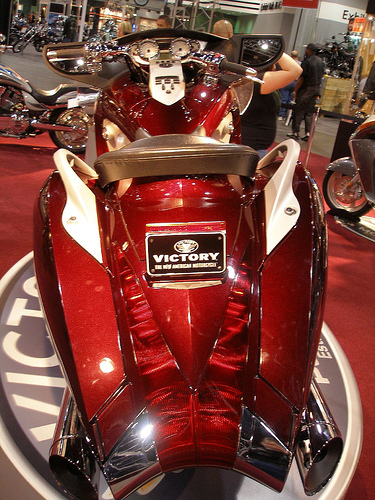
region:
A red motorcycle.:
[21, 11, 347, 495]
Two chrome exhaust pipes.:
[34, 379, 340, 494]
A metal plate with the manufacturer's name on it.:
[130, 216, 235, 291]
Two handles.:
[42, 113, 312, 259]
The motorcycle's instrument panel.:
[115, 30, 214, 75]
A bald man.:
[202, 8, 234, 50]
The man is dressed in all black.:
[282, 30, 328, 143]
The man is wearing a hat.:
[297, 37, 324, 63]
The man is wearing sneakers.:
[277, 111, 317, 149]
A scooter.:
[317, 101, 371, 226]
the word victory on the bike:
[153, 227, 243, 305]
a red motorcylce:
[30, 151, 365, 493]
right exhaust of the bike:
[276, 390, 346, 485]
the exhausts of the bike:
[0, 419, 336, 491]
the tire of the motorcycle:
[336, 114, 372, 198]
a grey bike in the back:
[37, 78, 88, 135]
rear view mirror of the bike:
[240, 16, 318, 75]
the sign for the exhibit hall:
[320, 2, 368, 127]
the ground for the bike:
[16, 313, 80, 451]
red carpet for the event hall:
[340, 253, 374, 352]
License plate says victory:
[144, 233, 225, 275]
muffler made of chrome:
[291, 378, 342, 495]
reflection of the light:
[100, 406, 159, 484]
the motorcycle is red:
[31, 27, 343, 499]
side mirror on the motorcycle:
[40, 43, 96, 76]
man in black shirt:
[286, 41, 326, 142]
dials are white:
[137, 37, 191, 60]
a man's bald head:
[210, 19, 233, 39]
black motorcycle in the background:
[12, 17, 69, 53]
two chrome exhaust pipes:
[49, 383, 343, 499]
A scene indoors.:
[6, 2, 360, 493]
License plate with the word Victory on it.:
[129, 221, 255, 284]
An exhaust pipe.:
[27, 374, 104, 498]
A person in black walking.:
[276, 25, 333, 155]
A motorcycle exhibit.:
[2, 4, 367, 465]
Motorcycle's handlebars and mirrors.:
[39, 29, 308, 101]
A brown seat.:
[86, 122, 284, 201]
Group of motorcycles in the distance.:
[5, 2, 81, 64]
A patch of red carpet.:
[2, 147, 373, 495]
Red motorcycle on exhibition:
[8, 7, 369, 494]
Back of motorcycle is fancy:
[20, 115, 330, 492]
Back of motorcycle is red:
[16, 121, 337, 491]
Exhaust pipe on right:
[286, 381, 346, 490]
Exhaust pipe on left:
[39, 380, 99, 494]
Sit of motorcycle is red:
[85, 122, 262, 195]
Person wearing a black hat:
[231, 23, 309, 155]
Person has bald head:
[206, 17, 241, 42]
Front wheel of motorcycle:
[316, 145, 373, 227]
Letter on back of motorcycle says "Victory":
[138, 230, 233, 283]